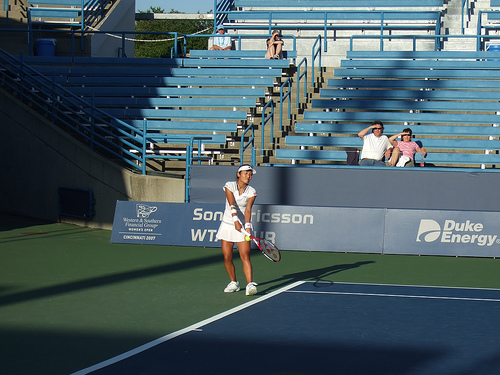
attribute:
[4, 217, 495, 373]
court — blue, green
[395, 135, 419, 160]
shirt — pink 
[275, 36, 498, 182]
bleachers — blue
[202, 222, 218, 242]
letter — white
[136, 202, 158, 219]
graphic — white 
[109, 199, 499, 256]
wall — blue 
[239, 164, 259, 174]
visor — white 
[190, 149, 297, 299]
player — female 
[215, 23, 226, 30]
hat — blue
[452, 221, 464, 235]
letter — white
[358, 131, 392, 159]
shirt — white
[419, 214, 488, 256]
letter — white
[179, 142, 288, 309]
asian woman — asian 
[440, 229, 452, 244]
letter — white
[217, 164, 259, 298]
tennis player — female 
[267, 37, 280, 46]
shirt — black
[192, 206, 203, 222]
letter — white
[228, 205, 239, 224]
objects — white